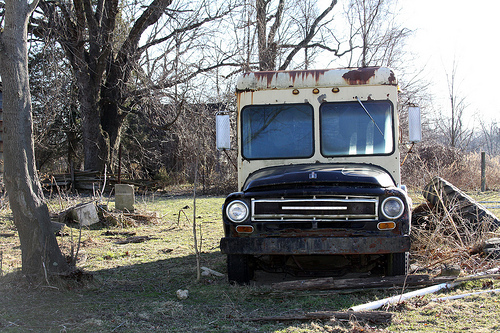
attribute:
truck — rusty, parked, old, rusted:
[225, 72, 414, 278]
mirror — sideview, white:
[408, 103, 426, 149]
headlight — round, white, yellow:
[381, 191, 407, 229]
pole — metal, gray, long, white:
[347, 282, 455, 313]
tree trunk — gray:
[4, 10, 72, 280]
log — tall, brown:
[267, 273, 434, 291]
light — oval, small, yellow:
[374, 220, 400, 230]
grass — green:
[144, 283, 175, 321]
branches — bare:
[283, 0, 400, 56]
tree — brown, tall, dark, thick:
[252, 4, 294, 74]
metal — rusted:
[355, 71, 366, 76]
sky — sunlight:
[426, 6, 498, 53]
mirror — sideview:
[209, 114, 235, 148]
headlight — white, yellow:
[225, 199, 247, 224]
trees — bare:
[14, 3, 382, 71]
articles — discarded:
[240, 272, 471, 333]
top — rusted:
[237, 68, 404, 86]